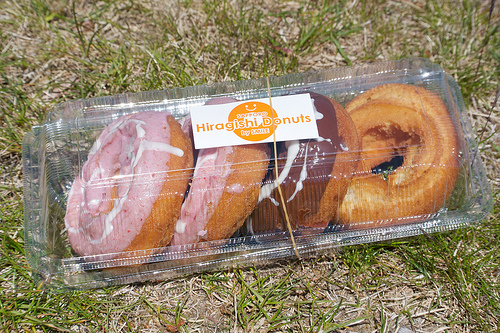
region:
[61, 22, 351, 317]
donuts in a container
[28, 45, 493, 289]
donuts in a clear container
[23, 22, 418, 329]
container on the grass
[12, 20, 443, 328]
clear container on the ground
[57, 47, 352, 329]
plastic containe ron the ground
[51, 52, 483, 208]
cooked donuts in a container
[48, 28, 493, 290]
a plastic container with cooked donuts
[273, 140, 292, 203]
There is a donut here with chocolate frosting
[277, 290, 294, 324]
There is a green patch of grass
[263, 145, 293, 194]
There is a rubber band here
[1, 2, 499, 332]
A clear plastic container of donuts on the ground.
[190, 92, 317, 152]
A white tag on top of the container lid.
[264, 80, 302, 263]
A rubber band around the container.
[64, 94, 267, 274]
Two pink frosted donuts with white frosting drizzled on top.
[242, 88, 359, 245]
A chocholate frosted donut with white drizzled frosting.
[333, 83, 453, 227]
A plain brown donut.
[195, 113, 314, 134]
The donut company name in orange letters.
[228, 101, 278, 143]
An orange circle with a smiley face on top.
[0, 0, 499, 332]
Grass and dirt on the ground.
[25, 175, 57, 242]
A package with donuts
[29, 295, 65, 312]
Grass next to package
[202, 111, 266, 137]
Lablel on the package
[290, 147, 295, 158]
Icing on a donut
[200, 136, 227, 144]
A white label on the package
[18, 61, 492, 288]
plastic case on donuts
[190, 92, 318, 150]
white sticker on plastic case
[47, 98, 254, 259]
white iced cake donuts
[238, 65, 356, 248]
chocolate frosting on donut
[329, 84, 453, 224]
one plain cake donut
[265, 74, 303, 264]
tan rubber band on package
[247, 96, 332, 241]
white frosting on chocolate frosted donuts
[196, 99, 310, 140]
orange writing on white sticker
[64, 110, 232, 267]
white frosting on pink icing